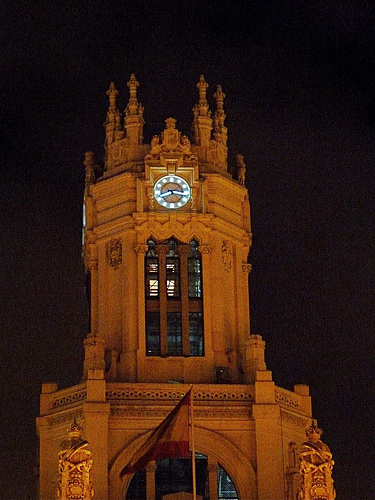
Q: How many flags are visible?
A: 1.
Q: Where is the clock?
A: On the tower.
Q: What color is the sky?
A: Black.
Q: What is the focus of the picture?
A: A building.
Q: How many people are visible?
A: Zero.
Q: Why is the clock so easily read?
A: It's illuminated.